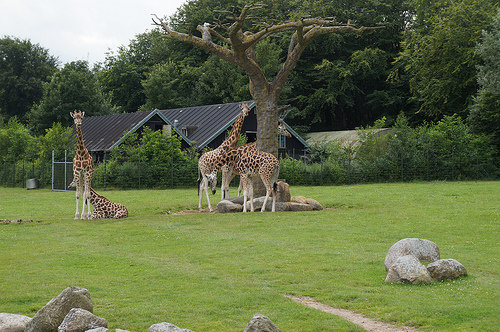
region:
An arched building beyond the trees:
[288, 111, 423, 182]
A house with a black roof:
[30, 100, 333, 175]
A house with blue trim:
[57, 88, 348, 225]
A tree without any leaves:
[128, 8, 400, 80]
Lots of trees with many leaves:
[2, 18, 495, 139]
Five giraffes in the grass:
[6, 55, 446, 315]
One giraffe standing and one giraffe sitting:
[38, 90, 140, 243]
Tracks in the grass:
[42, 219, 389, 326]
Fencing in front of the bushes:
[3, 134, 453, 190]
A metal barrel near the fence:
[23, 172, 41, 197]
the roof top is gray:
[87, 114, 123, 139]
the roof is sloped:
[97, 112, 117, 146]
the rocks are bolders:
[379, 215, 470, 292]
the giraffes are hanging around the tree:
[193, 102, 305, 217]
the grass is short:
[352, 177, 465, 210]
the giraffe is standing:
[58, 101, 95, 223]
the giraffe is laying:
[90, 176, 128, 224]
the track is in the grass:
[284, 260, 373, 312]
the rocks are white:
[378, 220, 464, 289]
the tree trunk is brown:
[251, 77, 290, 145]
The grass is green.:
[1, 180, 498, 330]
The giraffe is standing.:
[54, 105, 99, 225]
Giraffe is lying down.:
[66, 160, 139, 237]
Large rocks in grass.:
[371, 228, 471, 298]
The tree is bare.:
[147, 1, 381, 209]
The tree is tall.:
[148, 4, 378, 214]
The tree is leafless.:
[152, 0, 400, 220]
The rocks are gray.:
[372, 227, 472, 299]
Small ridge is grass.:
[263, 275, 420, 330]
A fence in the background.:
[5, 142, 499, 209]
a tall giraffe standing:
[65, 116, 95, 225]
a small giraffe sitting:
[68, 174, 130, 219]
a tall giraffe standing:
[191, 97, 248, 215]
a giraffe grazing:
[211, 142, 277, 216]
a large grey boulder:
[378, 233, 439, 270]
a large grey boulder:
[383, 253, 430, 287]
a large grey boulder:
[428, 254, 466, 279]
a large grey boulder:
[239, 309, 276, 328]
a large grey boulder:
[25, 283, 90, 328]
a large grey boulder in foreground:
[51, 304, 103, 329]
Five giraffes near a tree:
[6, 71, 329, 232]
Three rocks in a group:
[380, 231, 477, 286]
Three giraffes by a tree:
[133, 10, 383, 227]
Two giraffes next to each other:
[58, 103, 148, 257]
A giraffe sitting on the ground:
[60, 163, 168, 235]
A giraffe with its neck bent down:
[194, 135, 297, 217]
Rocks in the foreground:
[6, 221, 473, 331]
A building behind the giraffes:
[33, 96, 338, 175]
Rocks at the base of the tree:
[202, 173, 342, 235]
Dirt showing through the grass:
[266, 267, 441, 330]